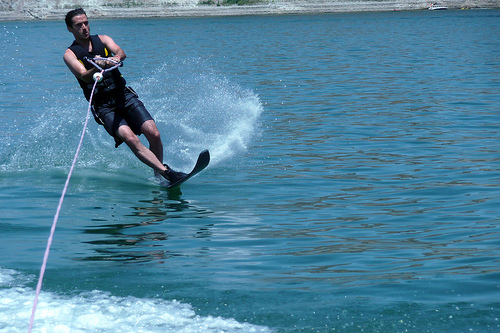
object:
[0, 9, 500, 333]
water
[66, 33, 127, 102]
vest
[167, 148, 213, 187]
water skiis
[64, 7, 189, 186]
man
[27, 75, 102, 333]
purple line